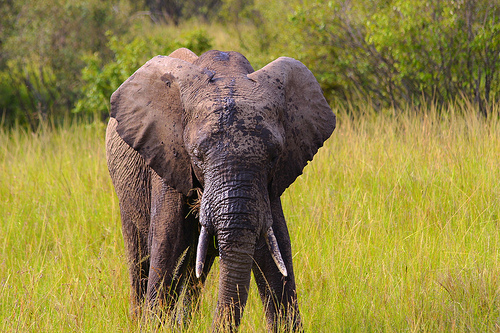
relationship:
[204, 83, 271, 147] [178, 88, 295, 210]
mud on face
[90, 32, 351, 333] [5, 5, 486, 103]
elephant standing in forest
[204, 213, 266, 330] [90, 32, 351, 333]
trunk of elephant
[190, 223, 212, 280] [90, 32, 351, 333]
tusk of elephant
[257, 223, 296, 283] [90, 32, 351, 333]
tusk of elephant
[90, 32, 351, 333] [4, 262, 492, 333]
elephant surrounded by grass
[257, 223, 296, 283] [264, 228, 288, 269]
tusk has black marks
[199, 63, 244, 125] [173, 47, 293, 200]
markings on head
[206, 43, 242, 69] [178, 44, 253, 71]
markings on back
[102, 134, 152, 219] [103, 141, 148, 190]
body has wrinkles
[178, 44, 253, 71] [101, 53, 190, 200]
hump behind ear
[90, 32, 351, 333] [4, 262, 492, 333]
elephant eats grass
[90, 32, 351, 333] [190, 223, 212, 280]
elephant has tusk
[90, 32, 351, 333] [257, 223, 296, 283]
elephant has tusk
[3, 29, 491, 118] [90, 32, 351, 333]
shrubs behind elephant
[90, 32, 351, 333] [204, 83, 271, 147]
elephant covered with mud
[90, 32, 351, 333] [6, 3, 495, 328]
elephant in wild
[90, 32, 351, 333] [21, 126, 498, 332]
elephant grazing in field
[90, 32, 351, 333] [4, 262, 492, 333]
elephant walking on grass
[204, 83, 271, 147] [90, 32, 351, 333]
mud on elephant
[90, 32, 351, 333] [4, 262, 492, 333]
elephant looking down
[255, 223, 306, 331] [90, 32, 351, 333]
leg of elephant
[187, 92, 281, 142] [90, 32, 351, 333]
forehead of elephant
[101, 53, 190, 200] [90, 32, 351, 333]
ear of elephant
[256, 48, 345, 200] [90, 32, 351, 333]
ear of elephant